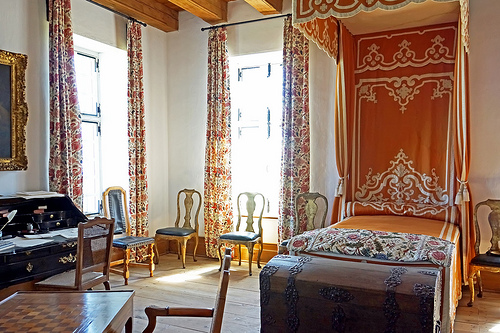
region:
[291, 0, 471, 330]
Bed with orange and white canopy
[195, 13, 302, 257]
Draped on side of large window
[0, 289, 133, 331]
Chess board on table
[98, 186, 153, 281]
Wooden chair with blue fabric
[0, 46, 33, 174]
Gold framed picture on wall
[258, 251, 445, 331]
Wooden cheast at foot of bed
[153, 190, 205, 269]
Chair with blue cushion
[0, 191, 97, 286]
Wood desk against wall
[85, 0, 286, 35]
Wood beams on ceiling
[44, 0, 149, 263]
Floral drapes on side of window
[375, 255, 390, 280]
edge of a bed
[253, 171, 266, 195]
part of a window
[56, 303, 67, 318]
part of a board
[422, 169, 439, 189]
part of a curtain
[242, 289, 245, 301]
part of the floor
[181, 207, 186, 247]
part of a chair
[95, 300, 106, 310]
part of a board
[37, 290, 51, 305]
edge of a boat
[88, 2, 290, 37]
wood beams on the ceiling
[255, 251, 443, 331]
a large brown wood trunk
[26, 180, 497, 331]
seven wood chairs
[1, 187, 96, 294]
a black writing desk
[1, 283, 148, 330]
an empty wood chess board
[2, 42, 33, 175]
gold picture frame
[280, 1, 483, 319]
tall canopy bed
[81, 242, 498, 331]
light colored wood floor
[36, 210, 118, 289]
wood chair with mesh back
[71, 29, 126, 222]
sun shining threw the window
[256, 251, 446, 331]
wooden trunk at foot of bed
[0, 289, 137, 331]
chess table next to chair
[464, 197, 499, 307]
chair next to the bed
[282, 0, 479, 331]
open bed curtains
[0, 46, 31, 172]
painting hanging on wall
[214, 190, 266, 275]
chair next to the window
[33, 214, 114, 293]
chair in front of desk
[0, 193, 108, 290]
black desk next to window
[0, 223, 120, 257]
paper on desk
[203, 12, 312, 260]
sunlight shining through window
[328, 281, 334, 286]
edge of a bed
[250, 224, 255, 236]
part of a chair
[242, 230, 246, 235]
edge of a chair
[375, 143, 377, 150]
part of a curtain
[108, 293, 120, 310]
part of a table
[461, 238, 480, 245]
part of a chair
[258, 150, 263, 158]
part of a window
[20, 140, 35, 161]
part of a painting